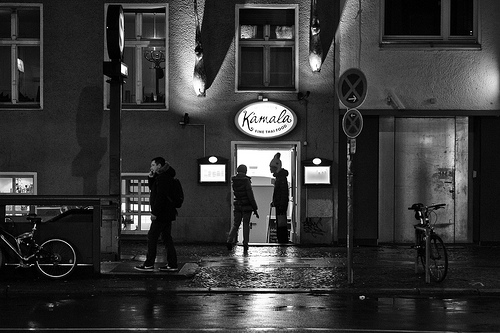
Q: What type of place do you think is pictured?
A: It is a restaurant.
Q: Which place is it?
A: It is a restaurant.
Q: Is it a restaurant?
A: Yes, it is a restaurant.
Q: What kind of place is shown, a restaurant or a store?
A: It is a restaurant.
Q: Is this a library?
A: No, it is a restaurant.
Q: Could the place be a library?
A: No, it is a restaurant.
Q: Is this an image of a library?
A: No, the picture is showing a restaurant.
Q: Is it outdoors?
A: Yes, it is outdoors.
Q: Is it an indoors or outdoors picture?
A: It is outdoors.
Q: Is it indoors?
A: No, it is outdoors.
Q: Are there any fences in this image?
A: No, there are no fences.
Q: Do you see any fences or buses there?
A: No, there are no fences or buses.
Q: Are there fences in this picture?
A: No, there are no fences.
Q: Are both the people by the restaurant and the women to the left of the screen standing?
A: Yes, both the people and the women are standing.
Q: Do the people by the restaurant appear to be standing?
A: Yes, the people are standing.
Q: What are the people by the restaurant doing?
A: The people are standing.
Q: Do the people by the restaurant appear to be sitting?
A: No, the people are standing.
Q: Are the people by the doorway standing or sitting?
A: The people are standing.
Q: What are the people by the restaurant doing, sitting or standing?
A: The people are standing.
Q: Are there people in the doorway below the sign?
A: Yes, there are people in the doorway.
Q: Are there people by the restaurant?
A: Yes, there are people by the restaurant.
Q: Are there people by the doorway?
A: Yes, there are people by the doorway.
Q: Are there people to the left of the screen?
A: Yes, there are people to the left of the screen.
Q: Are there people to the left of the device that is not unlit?
A: Yes, there are people to the left of the screen.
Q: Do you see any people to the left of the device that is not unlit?
A: Yes, there are people to the left of the screen.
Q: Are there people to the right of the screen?
A: No, the people are to the left of the screen.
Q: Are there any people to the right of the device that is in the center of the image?
A: No, the people are to the left of the screen.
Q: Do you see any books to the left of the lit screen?
A: No, there are people to the left of the screen.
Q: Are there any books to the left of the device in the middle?
A: No, there are people to the left of the screen.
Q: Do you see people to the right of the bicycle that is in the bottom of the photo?
A: Yes, there are people to the right of the bicycle.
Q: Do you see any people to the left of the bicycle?
A: No, the people are to the right of the bicycle.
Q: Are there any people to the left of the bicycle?
A: No, the people are to the right of the bicycle.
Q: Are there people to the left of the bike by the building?
A: Yes, there are people to the left of the bike.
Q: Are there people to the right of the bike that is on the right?
A: No, the people are to the left of the bike.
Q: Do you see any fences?
A: No, there are no fences.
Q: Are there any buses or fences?
A: No, there are no fences or buses.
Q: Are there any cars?
A: No, there are no cars.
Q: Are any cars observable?
A: No, there are no cars.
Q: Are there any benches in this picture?
A: No, there are no benches.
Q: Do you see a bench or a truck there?
A: No, there are no benches or trucks.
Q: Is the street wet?
A: Yes, the street is wet.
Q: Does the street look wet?
A: Yes, the street is wet.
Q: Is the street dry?
A: No, the street is wet.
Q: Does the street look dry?
A: No, the street is wet.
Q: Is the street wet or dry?
A: The street is wet.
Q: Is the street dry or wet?
A: The street is wet.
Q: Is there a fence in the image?
A: No, there are no fences.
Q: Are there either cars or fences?
A: No, there are no fences or cars.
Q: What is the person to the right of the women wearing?
A: The person is wearing a hat.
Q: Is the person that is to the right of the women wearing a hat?
A: Yes, the person is wearing a hat.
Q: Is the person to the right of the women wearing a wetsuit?
A: No, the person is wearing a hat.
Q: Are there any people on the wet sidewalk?
A: Yes, there is a person on the side walk.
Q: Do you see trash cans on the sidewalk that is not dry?
A: No, there is a person on the sidewalk.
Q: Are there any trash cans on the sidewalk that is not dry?
A: No, there is a person on the sidewalk.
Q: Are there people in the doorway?
A: Yes, there is a person in the doorway.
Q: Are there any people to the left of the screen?
A: Yes, there is a person to the left of the screen.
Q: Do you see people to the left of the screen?
A: Yes, there is a person to the left of the screen.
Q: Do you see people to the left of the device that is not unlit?
A: Yes, there is a person to the left of the screen.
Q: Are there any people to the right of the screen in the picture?
A: No, the person is to the left of the screen.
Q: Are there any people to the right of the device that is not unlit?
A: No, the person is to the left of the screen.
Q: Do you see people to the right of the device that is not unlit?
A: No, the person is to the left of the screen.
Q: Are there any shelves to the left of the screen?
A: No, there is a person to the left of the screen.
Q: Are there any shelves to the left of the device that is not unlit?
A: No, there is a person to the left of the screen.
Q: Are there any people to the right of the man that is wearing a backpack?
A: Yes, there is a person to the right of the man.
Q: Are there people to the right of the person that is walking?
A: Yes, there is a person to the right of the man.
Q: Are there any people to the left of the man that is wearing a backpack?
A: No, the person is to the right of the man.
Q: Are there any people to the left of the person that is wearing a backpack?
A: No, the person is to the right of the man.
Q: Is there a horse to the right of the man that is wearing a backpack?
A: No, there is a person to the right of the man.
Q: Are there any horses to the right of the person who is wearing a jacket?
A: No, there is a person to the right of the man.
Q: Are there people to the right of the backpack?
A: Yes, there is a person to the right of the backpack.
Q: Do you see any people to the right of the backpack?
A: Yes, there is a person to the right of the backpack.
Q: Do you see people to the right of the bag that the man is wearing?
A: Yes, there is a person to the right of the backpack.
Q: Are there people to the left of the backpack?
A: No, the person is to the right of the backpack.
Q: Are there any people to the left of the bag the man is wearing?
A: No, the person is to the right of the backpack.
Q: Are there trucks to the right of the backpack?
A: No, there is a person to the right of the backpack.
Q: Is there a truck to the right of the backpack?
A: No, there is a person to the right of the backpack.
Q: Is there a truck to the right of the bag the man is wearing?
A: No, there is a person to the right of the backpack.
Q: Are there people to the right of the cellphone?
A: Yes, there is a person to the right of the cellphone.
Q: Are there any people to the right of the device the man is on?
A: Yes, there is a person to the right of the cellphone.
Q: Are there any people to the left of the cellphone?
A: No, the person is to the right of the cellphone.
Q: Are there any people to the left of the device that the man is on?
A: No, the person is to the right of the cellphone.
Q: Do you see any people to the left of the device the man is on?
A: No, the person is to the right of the cellphone.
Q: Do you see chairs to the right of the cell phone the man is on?
A: No, there is a person to the right of the cellphone.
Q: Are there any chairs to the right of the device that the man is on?
A: No, there is a person to the right of the cellphone.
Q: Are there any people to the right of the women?
A: Yes, there is a person to the right of the women.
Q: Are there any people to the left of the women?
A: No, the person is to the right of the women.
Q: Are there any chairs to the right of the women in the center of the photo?
A: No, there is a person to the right of the women.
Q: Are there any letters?
A: Yes, there are letters.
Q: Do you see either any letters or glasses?
A: Yes, there are letters.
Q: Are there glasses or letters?
A: Yes, there are letters.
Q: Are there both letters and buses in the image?
A: No, there are letters but no buses.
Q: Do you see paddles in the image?
A: No, there are no paddles.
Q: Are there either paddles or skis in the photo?
A: No, there are no paddles or skis.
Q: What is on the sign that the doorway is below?
A: The letters are on the sign.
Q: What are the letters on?
A: The letters are on the sign.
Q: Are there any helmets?
A: No, there are no helmets.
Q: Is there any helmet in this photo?
A: No, there are no helmets.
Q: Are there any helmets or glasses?
A: No, there are no helmets or glasses.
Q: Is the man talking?
A: Yes, the man is talking.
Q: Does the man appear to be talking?
A: Yes, the man is talking.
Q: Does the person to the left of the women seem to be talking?
A: Yes, the man is talking.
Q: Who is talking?
A: The man is talking.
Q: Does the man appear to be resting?
A: No, the man is talking.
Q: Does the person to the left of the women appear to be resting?
A: No, the man is talking.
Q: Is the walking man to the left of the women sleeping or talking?
A: The man is talking.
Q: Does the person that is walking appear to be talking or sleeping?
A: The man is talking.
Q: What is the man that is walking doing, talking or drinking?
A: The man is talking.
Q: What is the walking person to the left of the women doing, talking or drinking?
A: The man is talking.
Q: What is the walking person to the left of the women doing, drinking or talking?
A: The man is talking.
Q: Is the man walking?
A: Yes, the man is walking.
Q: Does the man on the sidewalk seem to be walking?
A: Yes, the man is walking.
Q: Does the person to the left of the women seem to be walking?
A: Yes, the man is walking.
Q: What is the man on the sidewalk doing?
A: The man is walking.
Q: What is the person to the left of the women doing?
A: The man is walking.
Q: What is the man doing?
A: The man is walking.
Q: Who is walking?
A: The man is walking.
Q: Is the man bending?
A: No, the man is walking.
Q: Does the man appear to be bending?
A: No, the man is walking.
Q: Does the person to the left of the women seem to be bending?
A: No, the man is walking.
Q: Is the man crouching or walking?
A: The man is walking.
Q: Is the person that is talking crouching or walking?
A: The man is walking.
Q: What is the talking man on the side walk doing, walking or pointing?
A: The man is walking.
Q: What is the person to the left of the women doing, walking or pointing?
A: The man is walking.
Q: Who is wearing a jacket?
A: The man is wearing a jacket.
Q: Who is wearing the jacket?
A: The man is wearing a jacket.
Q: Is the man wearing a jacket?
A: Yes, the man is wearing a jacket.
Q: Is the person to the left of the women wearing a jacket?
A: Yes, the man is wearing a jacket.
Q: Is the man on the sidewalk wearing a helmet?
A: No, the man is wearing a jacket.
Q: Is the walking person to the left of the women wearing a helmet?
A: No, the man is wearing a jacket.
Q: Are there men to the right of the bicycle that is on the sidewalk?
A: Yes, there is a man to the right of the bicycle.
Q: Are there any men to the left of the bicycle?
A: No, the man is to the right of the bicycle.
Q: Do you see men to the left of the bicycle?
A: No, the man is to the right of the bicycle.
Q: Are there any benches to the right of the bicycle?
A: No, there is a man to the right of the bicycle.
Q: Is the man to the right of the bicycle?
A: Yes, the man is to the right of the bicycle.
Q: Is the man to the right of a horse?
A: No, the man is to the right of the bicycle.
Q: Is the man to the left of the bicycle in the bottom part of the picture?
A: No, the man is to the right of the bicycle.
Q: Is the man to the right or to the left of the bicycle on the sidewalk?
A: The man is to the right of the bicycle.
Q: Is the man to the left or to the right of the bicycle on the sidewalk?
A: The man is to the right of the bicycle.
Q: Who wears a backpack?
A: The man wears a backpack.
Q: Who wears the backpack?
A: The man wears a backpack.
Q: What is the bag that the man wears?
A: The bag is a backpack.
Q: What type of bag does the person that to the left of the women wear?
A: The man wears a backpack.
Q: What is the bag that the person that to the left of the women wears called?
A: The bag is a backpack.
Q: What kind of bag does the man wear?
A: The man wears a backpack.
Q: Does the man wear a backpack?
A: Yes, the man wears a backpack.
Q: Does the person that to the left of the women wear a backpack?
A: Yes, the man wears a backpack.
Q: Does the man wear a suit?
A: No, the man wears a backpack.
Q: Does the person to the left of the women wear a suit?
A: No, the man wears a backpack.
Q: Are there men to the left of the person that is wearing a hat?
A: Yes, there is a man to the left of the person.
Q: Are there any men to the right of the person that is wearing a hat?
A: No, the man is to the left of the person.